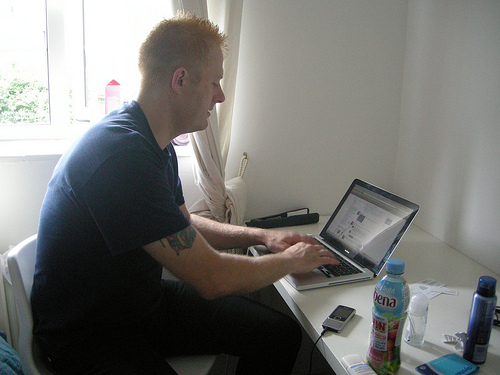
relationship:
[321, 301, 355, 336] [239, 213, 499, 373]
cell phone laying on table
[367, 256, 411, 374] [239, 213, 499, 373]
water bottle sitting on table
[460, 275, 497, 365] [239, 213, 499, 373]
spray can sitting on table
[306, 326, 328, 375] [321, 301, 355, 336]
cord connected to cell phone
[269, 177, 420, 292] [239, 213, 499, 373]
laptop sitting on table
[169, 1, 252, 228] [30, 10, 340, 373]
curtain next to man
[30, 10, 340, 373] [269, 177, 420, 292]
man using laptop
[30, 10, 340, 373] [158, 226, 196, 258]
man has a tattoo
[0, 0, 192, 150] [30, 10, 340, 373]
window next to man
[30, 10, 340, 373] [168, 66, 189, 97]
man has an ear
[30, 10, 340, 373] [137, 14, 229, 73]
man has hair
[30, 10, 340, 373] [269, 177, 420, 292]
man using a laptop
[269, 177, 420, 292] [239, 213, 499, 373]
laptop on table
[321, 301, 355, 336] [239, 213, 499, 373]
cell phone on table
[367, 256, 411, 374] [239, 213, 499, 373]
water bottle on table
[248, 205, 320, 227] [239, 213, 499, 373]
hair straightener on table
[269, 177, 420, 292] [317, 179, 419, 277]
laptop has a screen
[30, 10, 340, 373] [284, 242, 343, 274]
man has a hand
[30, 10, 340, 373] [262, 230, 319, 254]
man has a hand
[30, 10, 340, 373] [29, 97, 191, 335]
man wearing a shirt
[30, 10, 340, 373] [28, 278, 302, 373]
man wearing pants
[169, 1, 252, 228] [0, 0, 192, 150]
curtain tied beside window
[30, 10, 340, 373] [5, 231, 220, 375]
man sitting on a chair